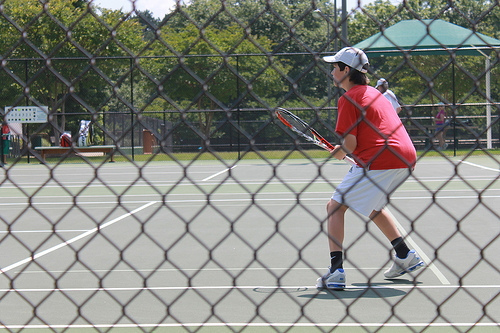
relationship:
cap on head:
[321, 45, 370, 74] [321, 47, 370, 90]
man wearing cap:
[314, 46, 423, 290] [318, 46, 372, 79]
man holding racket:
[314, 46, 423, 290] [274, 107, 359, 169]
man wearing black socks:
[314, 46, 423, 290] [390, 238, 410, 260]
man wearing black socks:
[314, 46, 423, 290] [328, 251, 345, 272]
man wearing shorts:
[314, 46, 423, 290] [337, 159, 408, 212]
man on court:
[314, 46, 423, 290] [0, 147, 500, 333]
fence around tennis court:
[4, 8, 484, 331] [5, 51, 492, 326]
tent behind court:
[350, 18, 498, 148] [0, 147, 500, 333]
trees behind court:
[133, 10, 314, 129] [73, 152, 298, 291]